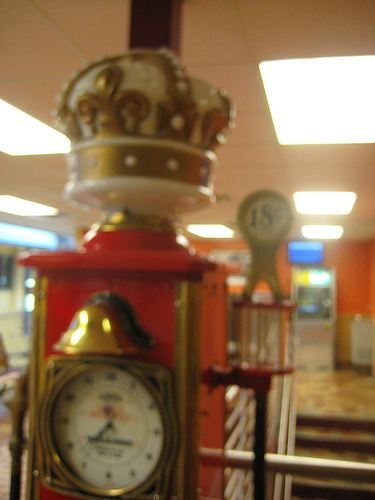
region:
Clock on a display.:
[34, 329, 202, 484]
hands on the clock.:
[76, 407, 219, 463]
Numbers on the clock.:
[80, 354, 140, 412]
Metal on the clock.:
[28, 288, 144, 389]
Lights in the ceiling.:
[276, 183, 367, 246]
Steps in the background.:
[270, 337, 356, 468]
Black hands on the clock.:
[73, 380, 119, 441]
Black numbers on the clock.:
[74, 358, 159, 460]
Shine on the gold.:
[76, 278, 140, 353]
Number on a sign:
[232, 171, 304, 254]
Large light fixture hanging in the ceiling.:
[245, 25, 373, 171]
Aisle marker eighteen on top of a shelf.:
[241, 189, 293, 304]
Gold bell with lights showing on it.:
[51, 292, 157, 357]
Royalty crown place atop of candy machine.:
[50, 47, 239, 220]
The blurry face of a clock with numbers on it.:
[47, 360, 168, 489]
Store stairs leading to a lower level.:
[297, 403, 370, 496]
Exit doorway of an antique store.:
[289, 264, 346, 387]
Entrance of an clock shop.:
[0, 218, 53, 356]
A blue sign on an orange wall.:
[284, 241, 331, 269]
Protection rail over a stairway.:
[204, 442, 374, 483]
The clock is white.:
[41, 372, 167, 484]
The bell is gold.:
[59, 296, 138, 358]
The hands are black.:
[80, 413, 120, 440]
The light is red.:
[25, 222, 247, 492]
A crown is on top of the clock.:
[45, 34, 242, 223]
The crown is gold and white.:
[47, 34, 232, 210]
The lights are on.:
[294, 179, 351, 249]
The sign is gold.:
[234, 192, 299, 305]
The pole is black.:
[246, 386, 278, 495]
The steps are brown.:
[303, 403, 363, 498]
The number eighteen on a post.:
[247, 196, 275, 236]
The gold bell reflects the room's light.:
[51, 296, 158, 358]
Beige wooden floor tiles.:
[306, 376, 351, 413]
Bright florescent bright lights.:
[297, 57, 364, 242]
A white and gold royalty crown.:
[51, 43, 239, 215]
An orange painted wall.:
[346, 254, 374, 293]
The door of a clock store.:
[297, 268, 336, 369]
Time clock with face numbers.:
[49, 355, 171, 496]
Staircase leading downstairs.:
[302, 396, 373, 497]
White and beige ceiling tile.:
[6, 4, 113, 50]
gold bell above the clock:
[47, 291, 156, 360]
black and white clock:
[46, 372, 163, 492]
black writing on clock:
[85, 433, 138, 453]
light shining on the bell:
[66, 306, 91, 346]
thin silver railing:
[201, 444, 372, 491]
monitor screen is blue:
[288, 239, 329, 263]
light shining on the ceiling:
[1, 198, 56, 222]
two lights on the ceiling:
[288, 182, 359, 252]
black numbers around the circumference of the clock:
[50, 371, 165, 492]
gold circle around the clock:
[21, 354, 182, 497]